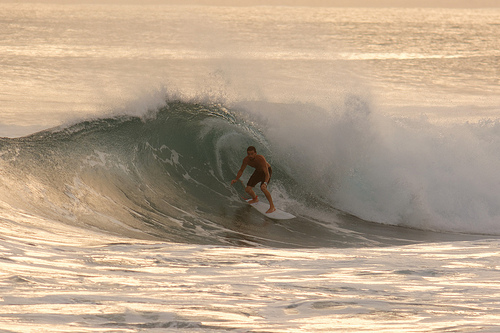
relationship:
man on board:
[229, 143, 283, 211] [242, 194, 299, 226]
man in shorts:
[229, 143, 283, 211] [242, 168, 275, 191]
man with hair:
[229, 143, 283, 211] [245, 145, 257, 151]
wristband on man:
[259, 180, 268, 185] [229, 143, 283, 211]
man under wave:
[229, 143, 283, 211] [15, 104, 495, 246]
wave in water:
[15, 104, 495, 246] [3, 2, 498, 327]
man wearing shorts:
[229, 143, 283, 211] [242, 168, 275, 191]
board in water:
[242, 194, 299, 226] [3, 2, 498, 327]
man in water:
[229, 143, 283, 211] [3, 2, 498, 327]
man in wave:
[229, 143, 283, 211] [15, 104, 495, 246]